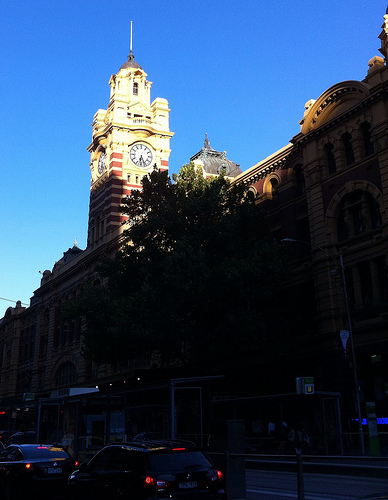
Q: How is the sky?
A: Clear.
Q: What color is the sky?
A: Blue.